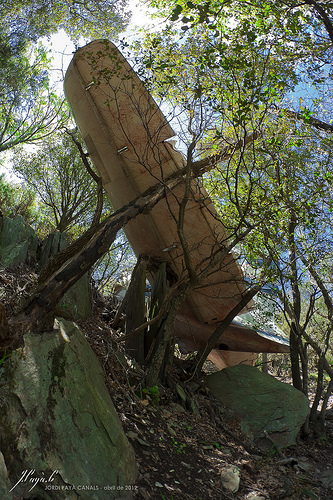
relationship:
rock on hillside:
[61, 40, 253, 338] [2, 220, 328, 500]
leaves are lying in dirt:
[202, 364, 310, 459] [2, 244, 329, 499]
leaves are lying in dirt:
[2, 320, 141, 492] [2, 244, 329, 499]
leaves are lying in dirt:
[37, 230, 97, 321] [2, 244, 329, 499]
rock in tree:
[61, 40, 253, 338] [145, 6, 330, 148]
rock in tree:
[61, 40, 253, 338] [198, 98, 331, 398]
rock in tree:
[61, 40, 253, 338] [0, 6, 133, 162]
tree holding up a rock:
[145, 6, 330, 148] [61, 40, 253, 338]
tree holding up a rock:
[198, 98, 331, 398] [61, 40, 253, 338]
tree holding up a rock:
[0, 6, 133, 162] [61, 40, 253, 338]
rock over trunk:
[61, 40, 253, 338] [20, 127, 257, 312]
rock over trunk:
[61, 40, 253, 338] [43, 127, 109, 280]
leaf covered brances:
[305, 197, 322, 214] [289, 186, 332, 216]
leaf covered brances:
[308, 166, 320, 185] [289, 186, 332, 216]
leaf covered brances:
[299, 174, 315, 189] [289, 186, 332, 216]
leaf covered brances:
[316, 197, 329, 207] [289, 186, 332, 216]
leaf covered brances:
[293, 177, 307, 185] [289, 186, 332, 216]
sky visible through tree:
[2, 1, 329, 321] [145, 6, 330, 148]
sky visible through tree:
[2, 1, 329, 321] [198, 98, 331, 398]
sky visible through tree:
[2, 1, 329, 321] [0, 6, 133, 162]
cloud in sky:
[0, 1, 294, 336] [2, 1, 329, 321]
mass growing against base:
[132, 378, 171, 403] [121, 312, 206, 381]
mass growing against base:
[177, 374, 198, 409] [121, 312, 206, 381]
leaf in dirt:
[190, 417, 209, 438] [2, 244, 329, 499]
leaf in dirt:
[204, 440, 234, 463] [2, 244, 329, 499]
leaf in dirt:
[188, 466, 205, 485] [2, 244, 329, 499]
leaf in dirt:
[173, 433, 192, 458] [2, 244, 329, 499]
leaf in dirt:
[154, 454, 173, 477] [2, 244, 329, 499]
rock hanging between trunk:
[61, 40, 253, 338] [20, 127, 257, 312]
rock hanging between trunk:
[61, 40, 253, 338] [43, 127, 109, 280]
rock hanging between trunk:
[61, 40, 253, 338] [148, 160, 284, 381]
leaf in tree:
[316, 197, 329, 207] [198, 98, 331, 398]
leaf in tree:
[305, 197, 322, 214] [145, 6, 330, 148]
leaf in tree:
[308, 166, 320, 185] [145, 6, 330, 148]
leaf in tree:
[299, 174, 315, 189] [145, 6, 330, 148]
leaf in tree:
[293, 177, 307, 185] [198, 98, 331, 398]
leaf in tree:
[308, 166, 320, 185] [198, 98, 331, 398]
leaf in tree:
[305, 197, 322, 214] [198, 98, 331, 398]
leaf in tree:
[299, 174, 315, 189] [198, 98, 331, 398]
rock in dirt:
[61, 40, 253, 338] [2, 244, 329, 499]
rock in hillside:
[61, 40, 253, 338] [2, 220, 328, 500]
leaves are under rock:
[202, 364, 310, 459] [61, 40, 253, 338]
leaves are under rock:
[2, 320, 141, 492] [61, 40, 253, 338]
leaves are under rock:
[37, 230, 97, 321] [61, 40, 253, 338]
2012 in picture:
[107, 486, 134, 496] [4, 1, 331, 500]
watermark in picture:
[8, 462, 150, 499] [4, 1, 331, 500]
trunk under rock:
[20, 127, 257, 312] [61, 40, 253, 338]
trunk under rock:
[43, 127, 109, 280] [61, 40, 253, 338]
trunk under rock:
[148, 160, 284, 381] [61, 40, 253, 338]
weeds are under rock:
[138, 252, 186, 287] [61, 40, 253, 338]